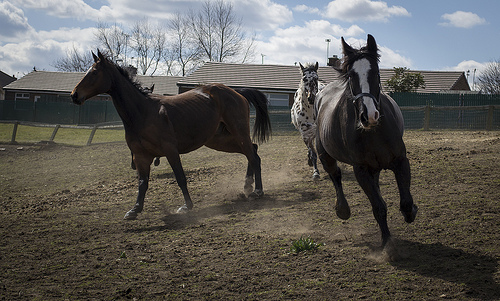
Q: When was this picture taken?
A: Daytime.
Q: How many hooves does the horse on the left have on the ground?
A: 4.